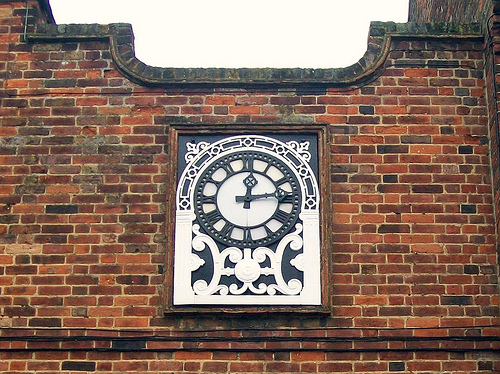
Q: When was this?
A: Daytime.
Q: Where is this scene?
A: Outside a building.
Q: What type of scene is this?
A: Outdoor.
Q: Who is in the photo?
A: No one.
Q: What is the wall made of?
A: Bricks.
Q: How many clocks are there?
A: One.